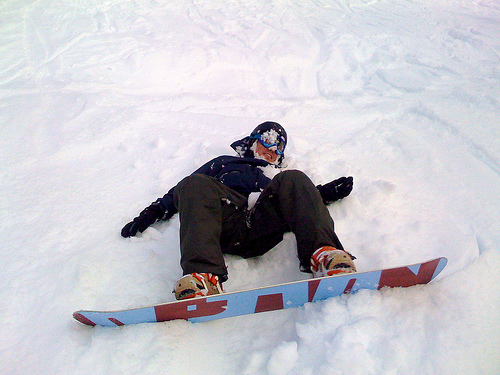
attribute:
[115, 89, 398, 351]
person — wearing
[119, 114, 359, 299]
man — laying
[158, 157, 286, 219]
jacket — black